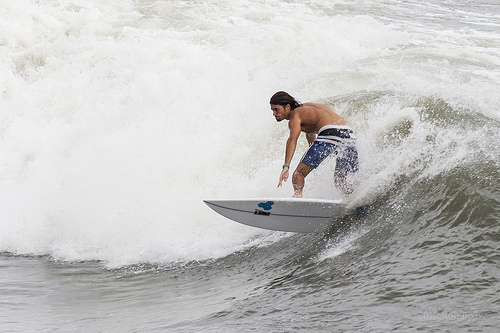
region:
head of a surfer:
[251, 64, 318, 133]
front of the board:
[197, 173, 266, 238]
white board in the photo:
[206, 169, 335, 256]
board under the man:
[199, 168, 342, 251]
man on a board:
[248, 77, 372, 190]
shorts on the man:
[289, 114, 370, 179]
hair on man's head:
[265, 83, 305, 112]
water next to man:
[335, 213, 435, 288]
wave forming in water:
[331, 134, 473, 279]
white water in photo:
[68, 118, 190, 231]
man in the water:
[177, 64, 414, 251]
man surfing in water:
[203, 62, 394, 232]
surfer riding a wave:
[169, 66, 396, 266]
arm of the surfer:
[261, 117, 309, 201]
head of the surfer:
[231, 67, 316, 154]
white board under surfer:
[151, 155, 371, 297]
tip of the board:
[179, 183, 277, 250]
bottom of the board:
[233, 197, 328, 241]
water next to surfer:
[274, 212, 431, 331]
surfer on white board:
[224, 77, 354, 246]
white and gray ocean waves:
[71, 230, 135, 282]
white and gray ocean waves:
[362, 286, 392, 307]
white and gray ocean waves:
[424, 253, 475, 288]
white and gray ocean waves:
[105, 178, 163, 229]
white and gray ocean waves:
[67, 258, 113, 295]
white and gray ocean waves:
[95, 94, 169, 159]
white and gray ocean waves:
[82, 67, 137, 109]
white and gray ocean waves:
[379, 55, 451, 102]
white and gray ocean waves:
[192, 43, 226, 82]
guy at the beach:
[152, 30, 494, 329]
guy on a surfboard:
[198, 51, 461, 288]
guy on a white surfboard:
[181, 51, 458, 311]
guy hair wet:
[178, 62, 438, 281]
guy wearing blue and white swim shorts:
[119, 32, 424, 282]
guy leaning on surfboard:
[178, 44, 448, 277]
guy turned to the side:
[175, 55, 450, 279]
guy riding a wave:
[28, 18, 482, 321]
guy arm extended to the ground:
[53, 17, 498, 329]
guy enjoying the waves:
[3, 1, 498, 326]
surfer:
[207, 70, 359, 247]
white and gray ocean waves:
[40, 136, 70, 184]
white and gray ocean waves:
[351, 256, 405, 312]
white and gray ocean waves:
[79, 213, 124, 267]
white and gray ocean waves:
[118, 130, 162, 176]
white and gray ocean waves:
[58, 220, 106, 282]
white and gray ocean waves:
[342, 40, 409, 94]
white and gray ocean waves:
[27, 38, 78, 93]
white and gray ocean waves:
[72, 35, 132, 80]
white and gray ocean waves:
[28, 162, 90, 236]